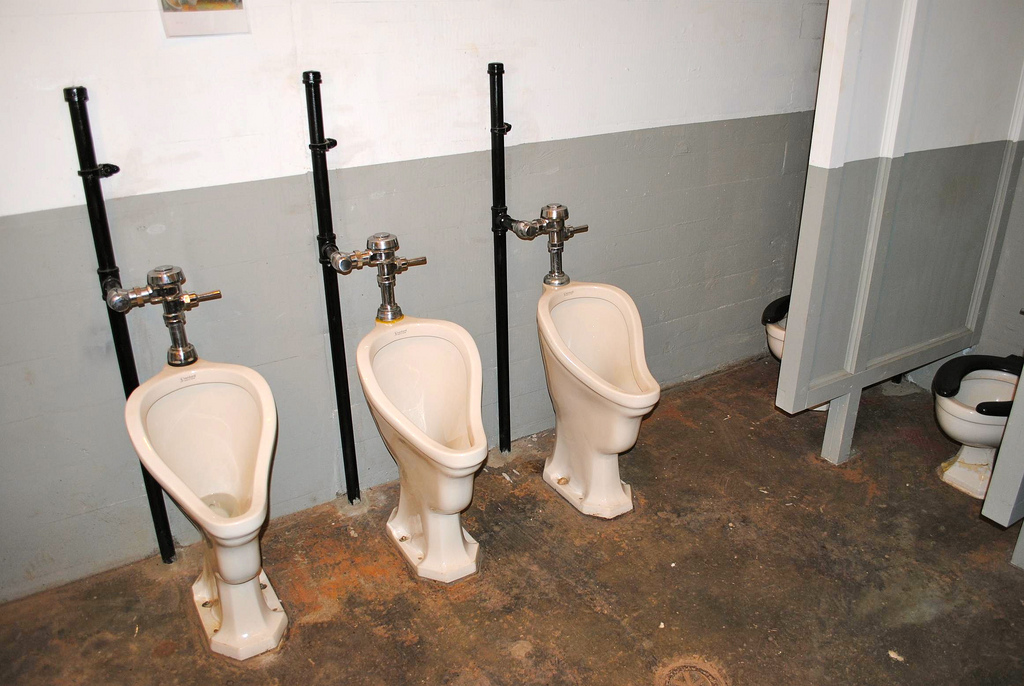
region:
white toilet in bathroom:
[120, 358, 349, 660]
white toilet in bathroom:
[340, 322, 518, 595]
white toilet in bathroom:
[508, 279, 683, 524]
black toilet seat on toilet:
[931, 335, 1018, 427]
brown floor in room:
[670, 478, 804, 644]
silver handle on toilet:
[397, 246, 433, 276]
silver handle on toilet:
[567, 217, 594, 238]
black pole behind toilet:
[473, 53, 537, 461]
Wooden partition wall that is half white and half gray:
[770, 2, 1021, 496]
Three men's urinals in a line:
[16, 76, 719, 655]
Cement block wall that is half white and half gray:
[13, 3, 805, 626]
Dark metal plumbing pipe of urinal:
[32, 81, 162, 585]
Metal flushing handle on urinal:
[180, 269, 223, 345]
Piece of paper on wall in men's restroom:
[145, 0, 270, 54]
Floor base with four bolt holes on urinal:
[158, 556, 314, 665]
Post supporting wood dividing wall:
[818, 386, 870, 476]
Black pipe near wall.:
[51, 88, 157, 602]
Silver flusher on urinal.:
[103, 262, 221, 355]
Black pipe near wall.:
[296, 76, 364, 456]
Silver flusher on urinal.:
[337, 240, 437, 301]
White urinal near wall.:
[362, 301, 492, 548]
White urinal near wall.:
[518, 274, 661, 491]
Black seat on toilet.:
[759, 285, 795, 327]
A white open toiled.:
[324, 241, 527, 592]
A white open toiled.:
[759, 273, 814, 363]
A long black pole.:
[60, 76, 187, 573]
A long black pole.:
[303, 65, 362, 505]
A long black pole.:
[483, 58, 521, 458]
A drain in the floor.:
[657, 662, 709, 682]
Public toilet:
[25, 18, 1018, 679]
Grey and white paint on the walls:
[8, 6, 1021, 515]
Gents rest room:
[22, 23, 1012, 672]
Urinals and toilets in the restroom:
[19, 38, 1022, 674]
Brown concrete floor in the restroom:
[6, 275, 1022, 671]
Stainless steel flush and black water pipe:
[40, 67, 224, 606]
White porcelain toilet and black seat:
[928, 337, 1023, 424]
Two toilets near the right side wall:
[710, 200, 1021, 521]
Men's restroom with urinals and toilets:
[38, 38, 1022, 630]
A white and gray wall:
[18, 50, 831, 503]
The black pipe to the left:
[35, 82, 223, 577]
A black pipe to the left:
[53, 75, 257, 563]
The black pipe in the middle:
[278, 56, 457, 524]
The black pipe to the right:
[480, 60, 558, 454]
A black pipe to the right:
[474, 57, 551, 470]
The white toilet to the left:
[104, 334, 352, 677]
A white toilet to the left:
[95, 353, 364, 676]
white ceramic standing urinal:
[99, 265, 315, 661]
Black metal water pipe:
[52, 78, 189, 566]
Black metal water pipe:
[285, 63, 368, 513]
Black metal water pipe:
[482, 61, 521, 455]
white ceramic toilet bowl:
[925, 341, 1023, 506]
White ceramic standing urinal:
[513, 200, 662, 524]